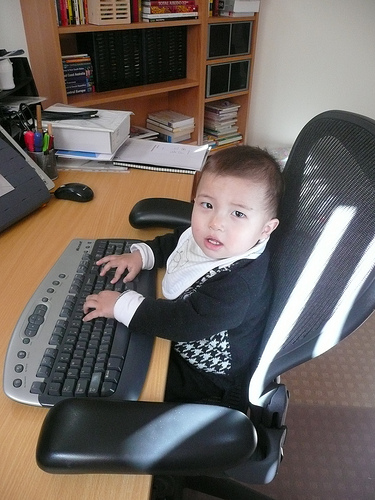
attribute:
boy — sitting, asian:
[79, 144, 283, 405]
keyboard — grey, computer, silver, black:
[5, 235, 159, 404]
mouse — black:
[52, 183, 95, 202]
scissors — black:
[14, 103, 37, 135]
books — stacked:
[61, 52, 97, 100]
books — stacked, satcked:
[144, 108, 195, 146]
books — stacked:
[203, 102, 245, 144]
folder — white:
[108, 135, 212, 173]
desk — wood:
[2, 170, 193, 499]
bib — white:
[160, 226, 274, 301]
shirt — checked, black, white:
[114, 227, 270, 390]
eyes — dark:
[195, 200, 251, 224]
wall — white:
[246, 5, 374, 158]